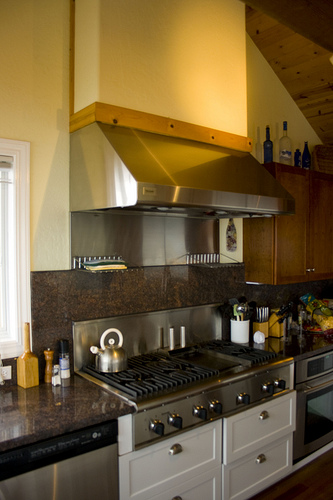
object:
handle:
[99, 326, 125, 349]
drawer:
[223, 388, 301, 469]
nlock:
[267, 307, 287, 340]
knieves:
[277, 300, 296, 317]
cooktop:
[73, 308, 300, 449]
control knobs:
[151, 377, 291, 439]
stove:
[74, 326, 305, 500]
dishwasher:
[1, 412, 119, 498]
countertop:
[1, 368, 136, 452]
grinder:
[43, 344, 54, 384]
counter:
[0, 371, 132, 500]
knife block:
[255, 304, 270, 322]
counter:
[233, 322, 333, 500]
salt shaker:
[51, 363, 62, 385]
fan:
[70, 125, 301, 225]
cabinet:
[243, 159, 333, 286]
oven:
[289, 351, 333, 479]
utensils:
[232, 298, 253, 322]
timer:
[253, 330, 266, 344]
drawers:
[223, 389, 300, 470]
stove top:
[70, 334, 298, 432]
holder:
[265, 310, 288, 339]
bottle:
[263, 125, 274, 165]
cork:
[265, 123, 270, 128]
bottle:
[278, 118, 293, 167]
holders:
[80, 253, 129, 278]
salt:
[51, 364, 63, 388]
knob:
[151, 420, 165, 435]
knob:
[168, 414, 184, 429]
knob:
[191, 406, 209, 419]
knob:
[209, 400, 223, 413]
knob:
[237, 391, 251, 407]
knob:
[261, 382, 271, 394]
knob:
[273, 376, 285, 388]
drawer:
[118, 414, 222, 498]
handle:
[169, 442, 184, 456]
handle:
[259, 409, 268, 420]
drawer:
[219, 431, 296, 498]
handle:
[255, 454, 267, 463]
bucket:
[230, 318, 251, 345]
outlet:
[1, 362, 19, 385]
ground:
[240, 446, 333, 500]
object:
[16, 316, 42, 389]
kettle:
[89, 326, 128, 374]